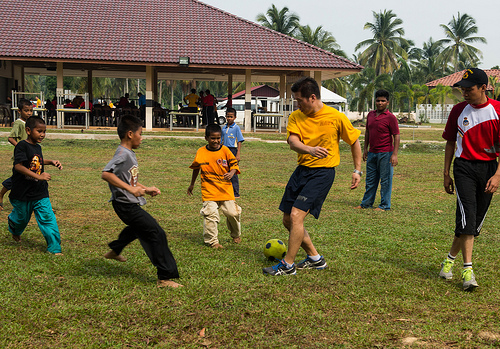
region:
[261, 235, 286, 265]
yellow and black soccer ball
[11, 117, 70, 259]
boy in black shirt and turquoise pants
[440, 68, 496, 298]
man in red and white shirt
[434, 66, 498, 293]
man looks down at soccer ball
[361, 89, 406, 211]
man in burgundy shirt watches from slight distance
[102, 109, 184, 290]
boy's right leg is outstretched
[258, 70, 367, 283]
man in yellow shirt about to kick the ball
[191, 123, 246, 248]
boy in orange shirt and khakis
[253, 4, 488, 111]
palm trees in background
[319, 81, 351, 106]
white awning in background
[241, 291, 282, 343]
The grass is green.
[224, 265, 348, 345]
The grass is green.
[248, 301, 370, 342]
The grass is green.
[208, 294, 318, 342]
The grass is green.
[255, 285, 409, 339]
The grass is green.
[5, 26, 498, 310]
a friendly soccer game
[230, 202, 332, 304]
a green and black ball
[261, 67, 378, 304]
a man in a yellow shirt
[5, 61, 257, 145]
a group of people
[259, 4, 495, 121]
three palm trees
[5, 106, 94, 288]
a barefoot boy in blue pants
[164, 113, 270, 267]
a boy in an orange shirt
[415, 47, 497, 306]
a guy in a baseball cap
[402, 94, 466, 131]
a white fence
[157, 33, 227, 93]
a light on a roof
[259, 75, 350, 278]
man kicking soccer ball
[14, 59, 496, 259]
children and adults playing soccer game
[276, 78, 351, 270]
athlete wears yellow shirt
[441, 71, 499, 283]
athlete wears white and red shirt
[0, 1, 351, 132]
big open building in background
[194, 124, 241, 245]
child playing soccer is happy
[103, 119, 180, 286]
child running toward the soccer ball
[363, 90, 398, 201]
man in red shirt watches game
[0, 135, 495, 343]
big soccer field covered in grass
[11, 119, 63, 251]
boy wears black shirt and blue pants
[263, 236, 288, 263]
an orange and blue ball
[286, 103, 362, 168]
an orange tee shirt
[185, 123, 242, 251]
a small, male child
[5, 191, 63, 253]
aqua colored jogging pants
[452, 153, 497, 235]
black shorts with white stripes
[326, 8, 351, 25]
a light blue sky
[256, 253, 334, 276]
a pair of sneakers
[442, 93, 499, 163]
a red and white shirt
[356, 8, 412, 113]
a tall palm tree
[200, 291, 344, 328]
green grass on ground